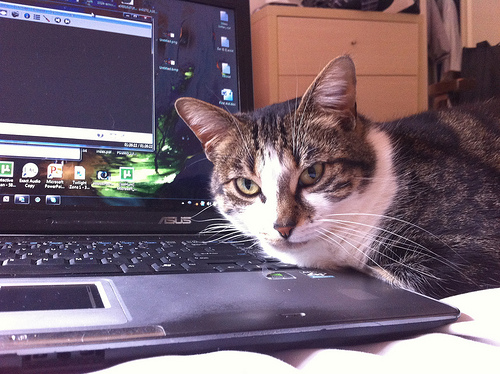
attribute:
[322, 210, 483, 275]
whisker — long, white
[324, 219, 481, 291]
whisker — long, white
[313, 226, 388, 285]
whisker — long, white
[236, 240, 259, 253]
whisker — long, white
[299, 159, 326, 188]
eye — yellow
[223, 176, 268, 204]
eye — yellow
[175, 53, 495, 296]
cat — shorthair, american, white, lying, grey, present, animal, indoors, looking, brown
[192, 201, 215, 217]
whisker — long, white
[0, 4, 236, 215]
screen — green, gold, dark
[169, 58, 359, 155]
ears — hairy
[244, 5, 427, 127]
cabinet — wooden, brown, light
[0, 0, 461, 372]
laptop — black, open, on, metal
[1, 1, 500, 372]
photo — clear